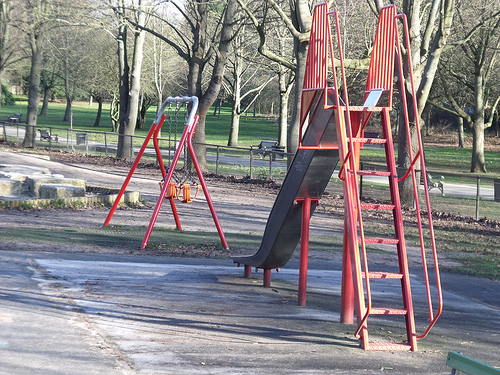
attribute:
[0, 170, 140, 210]
structure — grey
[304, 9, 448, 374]
slide — red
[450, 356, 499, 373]
top — green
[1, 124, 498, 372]
playground — public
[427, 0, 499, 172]
tree — brown, leafless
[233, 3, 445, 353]
slide — metal, red, tall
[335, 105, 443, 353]
ladder — red, metal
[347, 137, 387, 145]
rung — red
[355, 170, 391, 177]
rung — red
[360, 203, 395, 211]
rung — red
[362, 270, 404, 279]
rung — red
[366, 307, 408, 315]
rung — red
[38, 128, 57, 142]
bench — empty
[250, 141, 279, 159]
bench — empty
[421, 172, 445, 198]
bench — empty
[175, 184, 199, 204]
swing — orange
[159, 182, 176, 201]
swing — orange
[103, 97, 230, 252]
swingset — red, grey,and orange, orange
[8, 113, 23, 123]
bench — empty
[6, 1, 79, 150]
tree — brown, bare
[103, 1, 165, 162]
tree — brown, bare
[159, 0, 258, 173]
tree — brown, bare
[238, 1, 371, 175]
tree — brown, bare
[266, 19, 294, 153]
tree — brown, bare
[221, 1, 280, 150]
tree — brown, bare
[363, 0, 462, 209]
tree — brown, bare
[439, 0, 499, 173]
tree — brown, bare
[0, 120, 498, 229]
fence — metal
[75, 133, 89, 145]
waste basket — sitting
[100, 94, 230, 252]
swing set — red, small